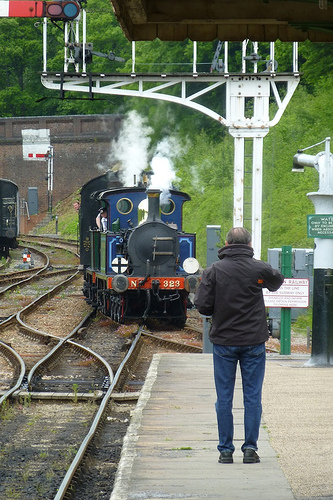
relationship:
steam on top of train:
[84, 97, 208, 190] [78, 171, 197, 327]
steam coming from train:
[84, 97, 208, 190] [78, 171, 197, 327]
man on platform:
[194, 228, 286, 465] [108, 351, 331, 499]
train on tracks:
[78, 171, 197, 327] [142, 323, 275, 355]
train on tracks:
[0, 178, 21, 257] [0, 254, 15, 268]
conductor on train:
[97, 206, 110, 229] [78, 171, 197, 327]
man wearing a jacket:
[194, 228, 286, 465] [192, 244, 286, 349]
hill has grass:
[35, 79, 331, 330] [38, 73, 329, 325]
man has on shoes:
[194, 228, 286, 465] [217, 448, 261, 464]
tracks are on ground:
[0, 254, 15, 268] [2, 234, 279, 499]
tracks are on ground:
[0, 313, 145, 498] [2, 234, 279, 499]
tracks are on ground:
[1, 239, 81, 331] [2, 234, 279, 499]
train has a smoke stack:
[78, 171, 197, 327] [106, 106, 183, 197]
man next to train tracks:
[194, 228, 286, 465] [2, 234, 279, 499]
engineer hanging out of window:
[97, 206, 110, 229] [94, 206, 108, 229]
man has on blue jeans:
[194, 228, 286, 465] [212, 342, 266, 452]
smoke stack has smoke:
[141, 189, 169, 220] [84, 97, 208, 190]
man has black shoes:
[194, 228, 286, 465] [217, 448, 261, 464]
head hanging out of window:
[99, 208, 111, 218] [94, 206, 108, 229]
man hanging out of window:
[97, 206, 110, 229] [94, 206, 108, 229]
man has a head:
[194, 228, 286, 465] [223, 228, 252, 246]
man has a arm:
[194, 228, 286, 465] [259, 260, 286, 293]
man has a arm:
[194, 228, 286, 465] [195, 265, 215, 317]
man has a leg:
[194, 228, 286, 465] [242, 343, 266, 452]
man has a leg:
[194, 228, 286, 465] [214, 343, 238, 450]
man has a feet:
[194, 228, 286, 465] [243, 447, 261, 463]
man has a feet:
[194, 228, 286, 465] [220, 446, 234, 464]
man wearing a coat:
[194, 228, 286, 465] [192, 244, 286, 349]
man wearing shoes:
[194, 228, 286, 465] [217, 448, 261, 464]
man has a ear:
[194, 228, 286, 465] [250, 239, 253, 249]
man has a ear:
[194, 228, 286, 465] [225, 238, 229, 246]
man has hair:
[194, 228, 286, 465] [223, 228, 252, 246]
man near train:
[194, 228, 286, 465] [78, 171, 197, 327]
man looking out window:
[97, 206, 110, 229] [94, 206, 108, 229]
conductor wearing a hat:
[97, 206, 110, 229] [97, 205, 107, 213]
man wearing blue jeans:
[194, 228, 286, 465] [212, 342, 266, 452]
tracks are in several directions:
[2, 234, 279, 499] [0, 264, 278, 403]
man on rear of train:
[72, 200, 81, 214] [80, 183, 92, 268]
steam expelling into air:
[84, 97, 208, 190] [0, 1, 331, 182]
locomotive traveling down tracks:
[78, 171, 197, 327] [142, 323, 275, 355]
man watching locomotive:
[194, 228, 286, 465] [78, 171, 197, 327]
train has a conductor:
[78, 171, 197, 327] [97, 206, 110, 229]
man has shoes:
[194, 228, 286, 465] [217, 448, 261, 464]